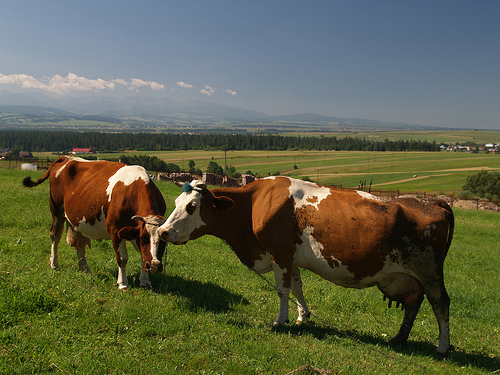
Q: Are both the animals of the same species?
A: Yes, all the animals are cows.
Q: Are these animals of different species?
A: No, all the animals are cows.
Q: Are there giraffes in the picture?
A: No, there are no giraffes.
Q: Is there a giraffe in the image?
A: No, there are no giraffes.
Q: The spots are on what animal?
A: The spots are on the cow.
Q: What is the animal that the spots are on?
A: The animal is a cow.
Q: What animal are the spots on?
A: The spots are on the cow.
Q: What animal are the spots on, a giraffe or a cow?
A: The spots are on a cow.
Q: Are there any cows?
A: Yes, there is a cow.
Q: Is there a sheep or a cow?
A: Yes, there is a cow.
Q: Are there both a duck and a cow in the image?
A: No, there is a cow but no ducks.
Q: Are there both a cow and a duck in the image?
A: No, there is a cow but no ducks.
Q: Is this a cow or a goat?
A: This is a cow.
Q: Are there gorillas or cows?
A: Yes, there is a cow.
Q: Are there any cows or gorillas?
A: Yes, there is a cow.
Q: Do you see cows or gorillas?
A: Yes, there is a cow.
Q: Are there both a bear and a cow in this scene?
A: No, there is a cow but no bears.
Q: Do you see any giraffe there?
A: No, there are no giraffes.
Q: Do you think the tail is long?
A: Yes, the tail is long.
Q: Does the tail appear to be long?
A: Yes, the tail is long.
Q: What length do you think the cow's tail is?
A: The tail is long.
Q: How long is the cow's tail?
A: The tail is long.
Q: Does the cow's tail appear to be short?
A: No, the tail is long.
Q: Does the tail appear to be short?
A: No, the tail is long.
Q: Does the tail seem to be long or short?
A: The tail is long.